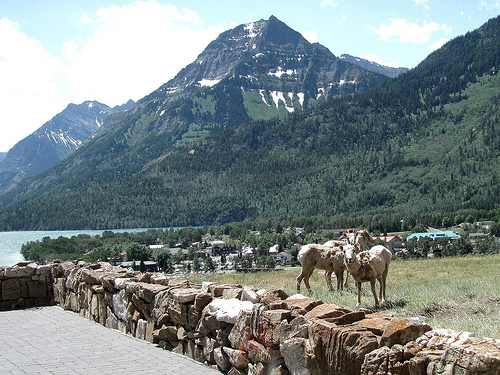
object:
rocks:
[265, 296, 287, 312]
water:
[0, 226, 216, 274]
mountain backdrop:
[0, 14, 499, 234]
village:
[370, 234, 407, 249]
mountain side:
[262, 74, 499, 171]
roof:
[372, 230, 402, 242]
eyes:
[350, 248, 358, 257]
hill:
[111, 98, 139, 112]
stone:
[373, 311, 436, 347]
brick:
[14, 332, 34, 344]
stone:
[193, 291, 213, 312]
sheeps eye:
[341, 247, 348, 253]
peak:
[231, 13, 313, 46]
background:
[0, 0, 498, 257]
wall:
[0, 261, 500, 375]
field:
[168, 252, 499, 343]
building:
[403, 229, 460, 245]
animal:
[333, 243, 392, 311]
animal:
[293, 227, 366, 297]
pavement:
[0, 305, 228, 374]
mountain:
[0, 13, 398, 232]